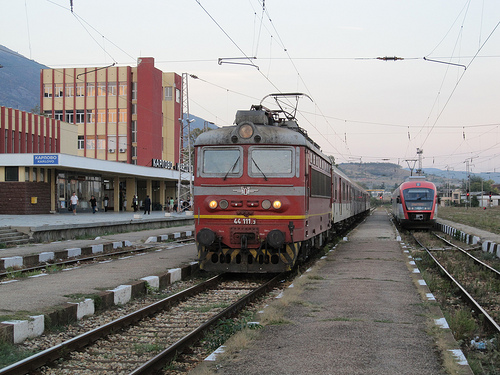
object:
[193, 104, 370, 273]
train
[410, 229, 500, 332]
railroad track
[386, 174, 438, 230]
train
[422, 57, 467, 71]
wire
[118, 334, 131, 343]
rock gravel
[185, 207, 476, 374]
pathway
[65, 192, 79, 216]
people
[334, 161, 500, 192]
hills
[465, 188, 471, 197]
lights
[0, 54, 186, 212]
buildings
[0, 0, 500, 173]
sky